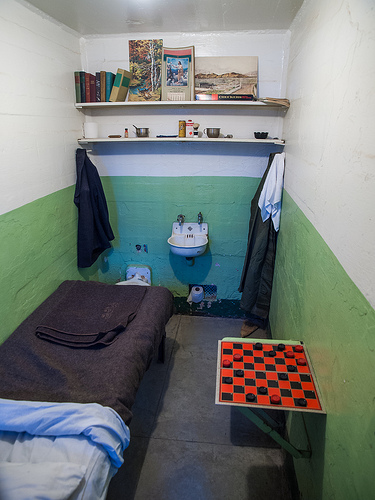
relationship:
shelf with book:
[75, 99, 293, 107] [111, 66, 132, 102]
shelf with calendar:
[75, 99, 293, 107] [161, 45, 194, 102]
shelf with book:
[75, 99, 293, 107] [105, 70, 110, 102]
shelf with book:
[75, 99, 293, 107] [85, 71, 97, 104]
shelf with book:
[75, 99, 293, 107] [74, 70, 82, 105]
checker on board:
[269, 392, 282, 406] [218, 339, 321, 412]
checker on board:
[254, 341, 265, 351] [218, 339, 321, 412]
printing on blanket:
[100, 298, 120, 325] [37, 278, 150, 351]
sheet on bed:
[0, 397, 135, 469] [1, 278, 177, 497]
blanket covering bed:
[2, 277, 178, 421] [1, 278, 177, 497]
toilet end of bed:
[118, 263, 153, 286] [1, 278, 177, 497]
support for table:
[234, 404, 311, 459] [218, 339, 321, 412]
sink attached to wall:
[169, 220, 211, 259] [78, 28, 293, 302]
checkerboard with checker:
[218, 339, 321, 412] [269, 392, 282, 406]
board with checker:
[217, 333, 321, 412] [269, 392, 282, 406]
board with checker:
[217, 333, 321, 412] [220, 358, 233, 369]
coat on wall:
[237, 153, 276, 327] [269, 1, 374, 497]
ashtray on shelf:
[253, 130, 269, 140] [79, 137, 288, 145]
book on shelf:
[99, 70, 108, 104] [75, 99, 293, 107]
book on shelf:
[96, 70, 101, 101] [75, 99, 293, 107]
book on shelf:
[79, 70, 85, 102] [75, 99, 293, 107]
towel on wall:
[258, 151, 284, 231] [269, 1, 374, 497]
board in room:
[217, 333, 321, 412] [1, 1, 372, 499]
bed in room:
[1, 278, 177, 497] [1, 1, 372, 499]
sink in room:
[169, 220, 211, 259] [1, 1, 372, 499]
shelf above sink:
[75, 99, 293, 107] [169, 220, 211, 259]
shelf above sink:
[79, 137, 288, 145] [169, 220, 211, 259]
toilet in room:
[118, 263, 153, 286] [1, 1, 372, 499]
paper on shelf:
[82, 119, 100, 142] [79, 137, 288, 145]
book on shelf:
[111, 66, 132, 102] [75, 99, 293, 107]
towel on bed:
[37, 278, 150, 351] [1, 278, 177, 497]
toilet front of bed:
[118, 263, 153, 286] [1, 278, 177, 497]